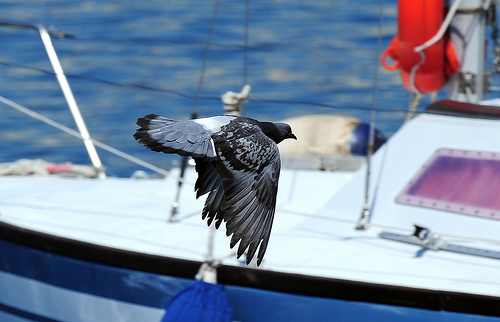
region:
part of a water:
[171, 18, 203, 45]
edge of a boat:
[349, 263, 372, 287]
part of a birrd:
[222, 149, 257, 213]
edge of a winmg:
[208, 211, 240, 264]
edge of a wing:
[255, 220, 275, 261]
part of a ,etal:
[351, 208, 379, 242]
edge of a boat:
[328, 258, 360, 293]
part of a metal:
[358, 178, 379, 236]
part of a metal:
[349, 159, 384, 220]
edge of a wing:
[223, 218, 250, 261]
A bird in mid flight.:
[124, 105, 314, 268]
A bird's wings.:
[181, 159, 285, 268]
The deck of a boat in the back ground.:
[1, 125, 156, 318]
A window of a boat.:
[393, 145, 498, 219]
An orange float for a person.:
[378, 0, 473, 96]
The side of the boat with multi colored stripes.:
[3, 226, 230, 320]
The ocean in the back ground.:
[76, 45, 161, 85]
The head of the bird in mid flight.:
[269, 118, 303, 146]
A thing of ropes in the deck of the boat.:
[3, 152, 132, 185]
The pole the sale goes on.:
[447, 0, 495, 92]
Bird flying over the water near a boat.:
[133, 113, 298, 266]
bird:
[131, 107, 307, 243]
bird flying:
[135, 108, 292, 246]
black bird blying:
[138, 102, 285, 246]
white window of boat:
[344, 119, 498, 259]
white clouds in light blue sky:
[79, 10, 169, 77]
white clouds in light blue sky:
[103, 62, 176, 90]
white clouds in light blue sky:
[119, 15, 255, 57]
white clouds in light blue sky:
[247, 12, 322, 60]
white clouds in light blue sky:
[264, 16, 318, 94]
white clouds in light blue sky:
[331, 13, 370, 104]